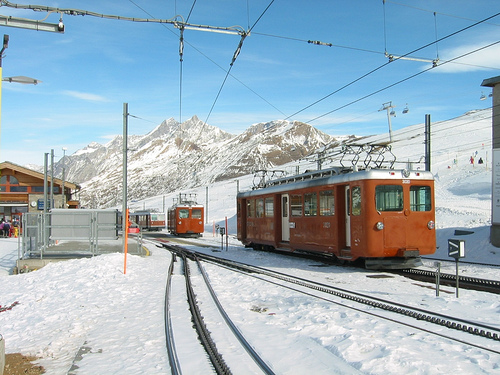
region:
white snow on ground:
[32, 272, 128, 317]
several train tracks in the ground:
[152, 260, 334, 340]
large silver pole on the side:
[107, 99, 151, 286]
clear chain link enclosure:
[16, 188, 147, 268]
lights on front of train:
[359, 217, 461, 234]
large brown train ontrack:
[224, 152, 452, 266]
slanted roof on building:
[15, 150, 100, 208]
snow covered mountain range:
[139, 98, 331, 153]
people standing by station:
[0, 205, 35, 243]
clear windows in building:
[13, 170, 59, 200]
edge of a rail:
[366, 279, 423, 321]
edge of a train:
[353, 200, 383, 249]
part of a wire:
[430, 97, 463, 142]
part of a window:
[383, 189, 396, 209]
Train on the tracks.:
[136, 169, 386, 276]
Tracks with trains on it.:
[140, 230, 394, 352]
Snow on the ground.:
[140, 223, 253, 358]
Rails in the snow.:
[117, 232, 286, 286]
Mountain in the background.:
[58, 71, 494, 250]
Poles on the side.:
[30, 128, 287, 320]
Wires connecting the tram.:
[231, 124, 415, 184]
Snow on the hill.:
[399, 125, 499, 199]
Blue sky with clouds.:
[55, 59, 232, 196]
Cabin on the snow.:
[1, 161, 88, 257]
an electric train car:
[235, 141, 436, 271]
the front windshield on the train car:
[375, 184, 405, 211]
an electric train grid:
[69, 0, 498, 142]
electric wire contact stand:
[244, 138, 406, 185]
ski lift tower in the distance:
[379, 97, 414, 139]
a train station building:
[0, 159, 80, 237]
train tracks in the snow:
[161, 245, 273, 374]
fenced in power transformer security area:
[20, 206, 123, 258]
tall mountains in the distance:
[61, 113, 236, 190]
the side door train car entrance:
[280, 192, 292, 243]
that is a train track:
[161, 243, 215, 373]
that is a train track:
[201, 265, 448, 320]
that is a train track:
[426, 268, 499, 286]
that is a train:
[231, 163, 443, 256]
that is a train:
[160, 199, 204, 234]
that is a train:
[129, 212, 164, 227]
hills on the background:
[42, 102, 331, 190]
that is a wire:
[148, 39, 189, 147]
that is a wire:
[197, 59, 224, 145]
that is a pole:
[116, 105, 138, 250]